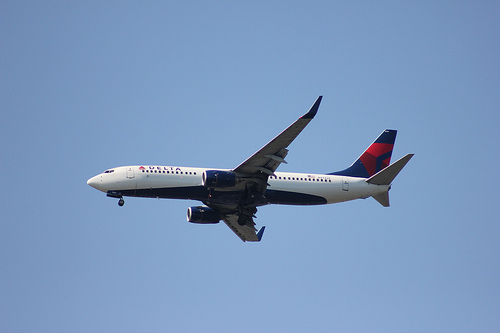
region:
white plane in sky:
[69, 100, 421, 241]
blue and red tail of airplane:
[349, 117, 404, 210]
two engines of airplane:
[182, 159, 232, 227]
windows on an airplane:
[130, 165, 206, 179]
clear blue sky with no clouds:
[50, 24, 212, 107]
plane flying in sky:
[72, 101, 411, 242]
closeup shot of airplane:
[76, 92, 424, 248]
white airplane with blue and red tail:
[85, 161, 393, 213]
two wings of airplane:
[221, 100, 290, 251]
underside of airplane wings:
[235, 115, 290, 251]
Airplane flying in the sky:
[36, 70, 448, 249]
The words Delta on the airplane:
[133, 162, 192, 174]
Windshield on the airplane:
[92, 164, 122, 175]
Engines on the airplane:
[180, 150, 242, 245]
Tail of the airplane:
[349, 117, 419, 219]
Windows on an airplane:
[135, 166, 198, 177]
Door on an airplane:
[337, 169, 359, 203]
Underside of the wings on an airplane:
[210, 107, 326, 259]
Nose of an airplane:
[81, 150, 132, 217]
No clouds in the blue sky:
[25, 23, 496, 273]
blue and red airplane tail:
[342, 128, 408, 174]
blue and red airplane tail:
[359, 113, 391, 182]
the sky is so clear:
[305, 274, 353, 311]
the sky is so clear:
[323, 237, 413, 317]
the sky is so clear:
[292, 223, 385, 313]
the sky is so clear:
[291, 241, 341, 316]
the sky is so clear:
[332, 261, 388, 307]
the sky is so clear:
[311, 190, 358, 250]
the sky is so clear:
[296, 270, 378, 321]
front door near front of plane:
[118, 164, 145, 184]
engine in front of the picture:
[198, 164, 244, 194]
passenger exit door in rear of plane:
[338, 174, 360, 204]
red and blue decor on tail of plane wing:
[351, 127, 428, 189]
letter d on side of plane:
[145, 157, 157, 176]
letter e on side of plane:
[152, 159, 162, 179]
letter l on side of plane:
[155, 157, 176, 177]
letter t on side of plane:
[166, 163, 178, 177]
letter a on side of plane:
[171, 163, 190, 177]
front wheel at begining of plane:
[106, 194, 144, 219]